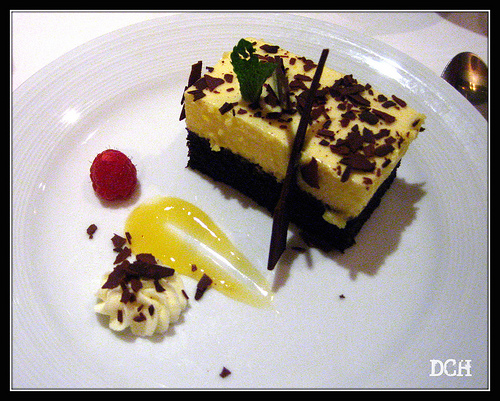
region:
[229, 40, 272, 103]
Green garnish on cake.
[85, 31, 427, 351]
Dessert served on plate.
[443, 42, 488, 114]
Spoon on side of dessert plate.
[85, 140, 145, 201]
Raspberry served on plate.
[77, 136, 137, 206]
One single fresh raspberry.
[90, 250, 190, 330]
A dollop of cream top with chocolate shavings.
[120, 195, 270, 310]
Yellow gel served near cake.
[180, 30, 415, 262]
Square cut of cake on plate.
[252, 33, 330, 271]
Long piece of chocolate shaving.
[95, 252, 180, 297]
Chocolate shavings on top of cream.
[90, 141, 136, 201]
A red raspberry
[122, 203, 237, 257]
A swish of cream sauce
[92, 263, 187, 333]
A dallop of cream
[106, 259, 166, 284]
Chocolate shavings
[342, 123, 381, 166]
Chocolate shavings on the dessert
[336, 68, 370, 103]
Chocolate shavings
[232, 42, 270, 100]
A twig of fresh mint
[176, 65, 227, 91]
Chocolate shavings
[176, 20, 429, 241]
A chocolate dessert on a plate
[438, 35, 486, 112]
A silver spoon next to the plate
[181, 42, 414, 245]
cake on the plate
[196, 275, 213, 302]
chocolate sliver on plate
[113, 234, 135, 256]
chocolate sliver on plate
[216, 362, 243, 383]
chocolate sliver on plate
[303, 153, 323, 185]
chocolate sliver on plate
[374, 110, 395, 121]
chocolate sliver on plate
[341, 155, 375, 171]
chocolate sliver on plate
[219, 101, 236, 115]
chocolate sliver on plate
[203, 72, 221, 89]
chocolate sliver on plate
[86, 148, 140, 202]
A red raspberry.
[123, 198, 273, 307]
Yellow smear on a white plate.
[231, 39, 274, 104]
Green stuff on top of a piece of cake.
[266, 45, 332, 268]
Long piece of chocolate on a cake.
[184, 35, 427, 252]
Chocolate and yellow cake with chocolate on top.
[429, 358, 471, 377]
White letters DCH.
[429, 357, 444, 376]
A white letter D.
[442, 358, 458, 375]
A white letter C.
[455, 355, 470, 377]
A white letter H.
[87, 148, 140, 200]
A red raspberry by a yellow smear.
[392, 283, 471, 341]
the plate is white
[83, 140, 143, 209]
the raspberry is red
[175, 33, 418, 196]
the cake is on the plate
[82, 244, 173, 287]
the chocolate is on the plate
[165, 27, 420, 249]
the cake is rectangular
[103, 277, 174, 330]
the icing is white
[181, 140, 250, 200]
the bottom layer is chocolate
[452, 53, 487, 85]
the spoon is shiney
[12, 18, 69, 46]
the table is white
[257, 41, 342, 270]
a piece of chocolate is in the cake